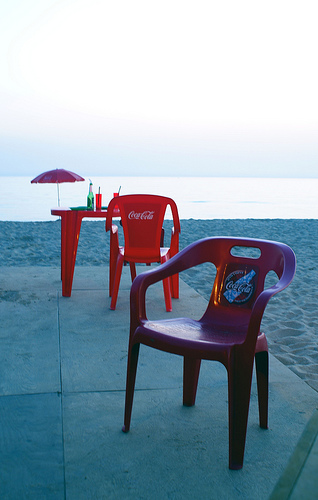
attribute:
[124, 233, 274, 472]
chair — plastic, maroon, red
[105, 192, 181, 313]
chair — plastic, red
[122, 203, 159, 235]
coca cola logo — white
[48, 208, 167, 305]
table — red, plastic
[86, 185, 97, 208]
bottle — green, glass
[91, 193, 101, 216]
tumbler — red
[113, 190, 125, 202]
tumbler — red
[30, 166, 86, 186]
umbrella — red, wide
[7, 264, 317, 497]
floor — checkered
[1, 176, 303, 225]
water — wavy, calm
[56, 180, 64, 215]
rod — metal, long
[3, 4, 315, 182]
sky — pale blue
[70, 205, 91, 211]
plate — green